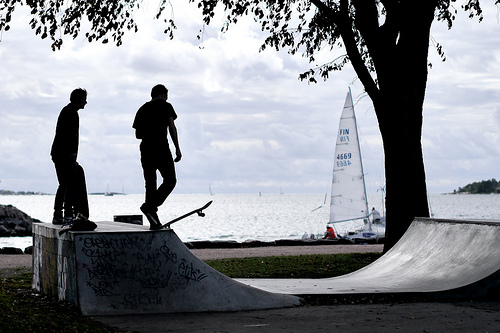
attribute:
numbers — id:
[330, 148, 367, 176]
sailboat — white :
[12, 179, 285, 270]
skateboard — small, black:
[162, 194, 218, 231]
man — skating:
[131, 81, 183, 230]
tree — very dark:
[1, 1, 484, 254]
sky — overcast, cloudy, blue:
[2, 2, 483, 191]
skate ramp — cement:
[29, 213, 484, 317]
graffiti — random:
[72, 226, 214, 314]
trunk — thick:
[365, 108, 433, 222]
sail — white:
[327, 90, 368, 222]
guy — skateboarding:
[131, 81, 181, 231]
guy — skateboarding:
[49, 87, 90, 226]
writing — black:
[334, 125, 353, 167]